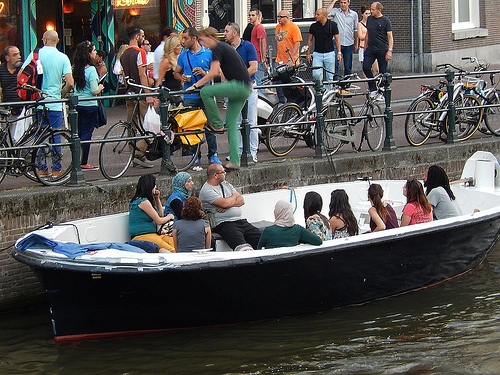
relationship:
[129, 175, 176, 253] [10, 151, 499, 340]
person sitting in boat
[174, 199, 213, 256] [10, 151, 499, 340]
person sitting in boat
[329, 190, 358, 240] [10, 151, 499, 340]
person sitting in boat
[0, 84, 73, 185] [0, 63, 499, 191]
bicycle on walkway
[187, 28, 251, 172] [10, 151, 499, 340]
person climbing into or out boat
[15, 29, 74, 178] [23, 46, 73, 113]
person in shirt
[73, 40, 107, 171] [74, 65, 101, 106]
person in shirt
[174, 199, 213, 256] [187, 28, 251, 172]
person looking at person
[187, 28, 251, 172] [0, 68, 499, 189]
person on railing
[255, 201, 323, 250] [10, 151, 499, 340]
woman on bus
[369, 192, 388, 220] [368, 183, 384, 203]
tail coming off head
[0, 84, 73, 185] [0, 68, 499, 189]
bicycle against railing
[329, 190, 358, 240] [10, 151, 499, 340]
girl sitting on boat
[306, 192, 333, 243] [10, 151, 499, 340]
girl sitting on boat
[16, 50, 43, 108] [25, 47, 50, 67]
backpack on shoulder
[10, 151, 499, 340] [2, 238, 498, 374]
boat in water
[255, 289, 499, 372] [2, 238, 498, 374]
ripples are in water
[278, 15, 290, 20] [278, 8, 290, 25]
glasses on head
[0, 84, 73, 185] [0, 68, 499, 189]
bicycle leaning against railing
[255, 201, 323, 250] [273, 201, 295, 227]
woman wearing head wrap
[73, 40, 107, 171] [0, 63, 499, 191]
person walking on walkway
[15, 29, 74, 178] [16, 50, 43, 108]
person with backpack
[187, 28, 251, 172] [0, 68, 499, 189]
person climbing over railing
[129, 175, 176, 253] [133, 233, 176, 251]
person wearing yellow pants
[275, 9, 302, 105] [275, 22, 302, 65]
man with t-shirt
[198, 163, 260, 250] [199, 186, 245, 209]
man sitting with arms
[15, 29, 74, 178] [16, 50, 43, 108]
person carrying backpack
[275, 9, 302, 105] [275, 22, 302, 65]
man wearing t-shirt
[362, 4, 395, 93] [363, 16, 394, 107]
person dressed in black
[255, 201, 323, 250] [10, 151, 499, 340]
woman sitting in boat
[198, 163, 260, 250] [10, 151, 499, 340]
man sitting in boat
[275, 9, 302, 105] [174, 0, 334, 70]
man next to building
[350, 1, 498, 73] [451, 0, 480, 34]
building with window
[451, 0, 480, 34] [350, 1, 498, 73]
window on building